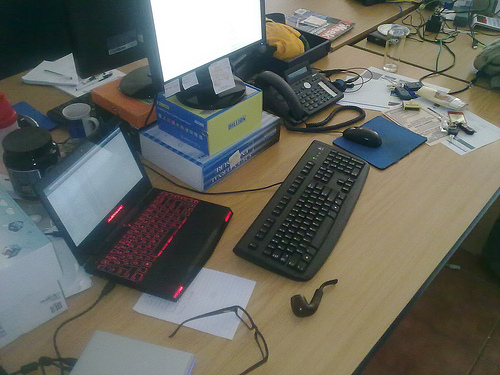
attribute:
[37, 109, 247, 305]
laptop — open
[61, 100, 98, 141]
cup — empty